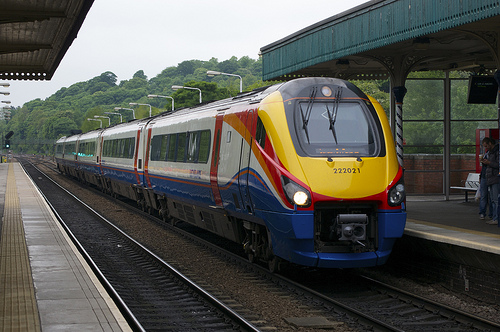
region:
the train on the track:
[53, 75, 405, 265]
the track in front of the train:
[281, 273, 498, 330]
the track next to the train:
[13, 153, 259, 330]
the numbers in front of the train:
[332, 165, 361, 173]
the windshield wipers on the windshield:
[303, 85, 345, 146]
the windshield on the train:
[294, 95, 379, 157]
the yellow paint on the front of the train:
[256, 88, 400, 197]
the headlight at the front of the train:
[293, 190, 307, 205]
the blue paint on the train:
[52, 157, 404, 274]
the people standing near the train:
[478, 137, 499, 222]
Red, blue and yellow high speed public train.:
[53, 77, 413, 269]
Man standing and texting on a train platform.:
[479, 136, 496, 228]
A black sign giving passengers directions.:
[464, 70, 496, 106]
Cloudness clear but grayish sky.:
[111, 5, 270, 44]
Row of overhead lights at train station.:
[79, 84, 265, 124]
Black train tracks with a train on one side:
[126, 241, 436, 330]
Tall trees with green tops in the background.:
[42, 60, 222, 106]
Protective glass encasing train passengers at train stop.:
[411, 63, 449, 196]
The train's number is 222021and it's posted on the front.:
[328, 166, 365, 173]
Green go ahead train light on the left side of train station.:
[5, 142, 13, 152]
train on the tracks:
[32, 73, 432, 275]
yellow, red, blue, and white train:
[40, 86, 424, 292]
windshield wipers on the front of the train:
[291, 84, 357, 155]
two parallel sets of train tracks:
[28, 150, 478, 330]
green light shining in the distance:
[2, 142, 14, 152]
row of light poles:
[82, 64, 247, 136]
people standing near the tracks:
[459, 140, 499, 225]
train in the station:
[1, 0, 499, 322]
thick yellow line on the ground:
[3, 160, 40, 330]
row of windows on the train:
[144, 125, 221, 171]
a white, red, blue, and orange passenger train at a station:
[51, 69, 405, 267]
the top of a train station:
[255, 17, 345, 82]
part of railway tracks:
[338, 287, 454, 322]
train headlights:
[288, 170, 405, 215]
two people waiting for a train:
[463, 130, 499, 227]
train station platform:
[1, 172, 36, 330]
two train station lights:
[143, 83, 204, 105]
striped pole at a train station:
[387, 70, 410, 157]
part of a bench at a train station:
[451, 170, 478, 207]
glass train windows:
[149, 130, 212, 163]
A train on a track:
[42, 78, 430, 272]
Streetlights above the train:
[67, 68, 247, 130]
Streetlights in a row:
[78, 61, 244, 127]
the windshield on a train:
[288, 85, 388, 173]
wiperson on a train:
[293, 73, 343, 147]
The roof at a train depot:
[252, 5, 499, 92]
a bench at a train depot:
[451, 157, 481, 197]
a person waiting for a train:
[470, 129, 498, 219]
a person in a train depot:
[470, 122, 498, 228]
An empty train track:
[10, 183, 219, 331]